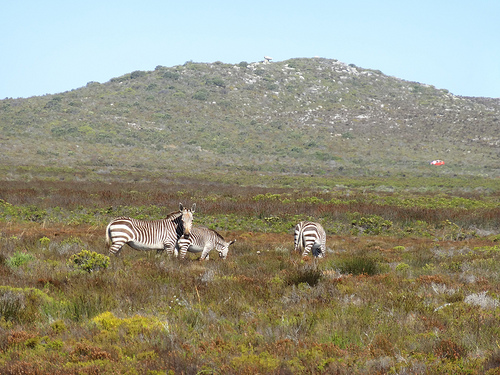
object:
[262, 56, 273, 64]
goat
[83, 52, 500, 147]
rocks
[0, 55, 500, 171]
hill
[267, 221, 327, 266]
zebras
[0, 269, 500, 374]
grass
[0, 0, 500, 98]
sky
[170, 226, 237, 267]
zebra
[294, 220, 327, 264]
zebra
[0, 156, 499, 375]
valley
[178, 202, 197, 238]
head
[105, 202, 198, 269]
zebra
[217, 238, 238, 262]
head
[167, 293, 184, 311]
flowers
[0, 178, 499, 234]
plants